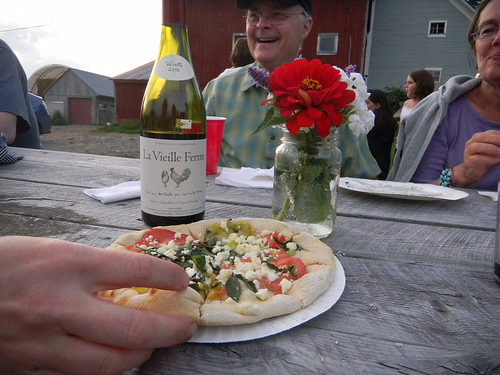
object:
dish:
[175, 251, 346, 345]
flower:
[246, 66, 272, 93]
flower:
[344, 63, 360, 78]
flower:
[334, 66, 376, 136]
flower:
[296, 53, 304, 61]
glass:
[202, 115, 226, 178]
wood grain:
[399, 231, 489, 263]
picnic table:
[0, 137, 496, 374]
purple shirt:
[415, 102, 496, 186]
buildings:
[133, 0, 500, 150]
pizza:
[66, 217, 337, 327]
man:
[195, 0, 385, 173]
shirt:
[184, 59, 379, 188]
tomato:
[288, 258, 305, 277]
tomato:
[265, 280, 283, 294]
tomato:
[266, 233, 284, 248]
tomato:
[135, 228, 200, 245]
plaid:
[230, 101, 240, 116]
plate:
[337, 176, 469, 204]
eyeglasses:
[242, 12, 307, 26]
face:
[243, 3, 300, 63]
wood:
[2, 144, 499, 371]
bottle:
[136, 0, 210, 230]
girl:
[394, 69, 449, 164]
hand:
[0, 234, 197, 373]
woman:
[392, 13, 498, 183]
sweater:
[393, 74, 470, 165]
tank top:
[399, 104, 414, 119]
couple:
[197, 2, 500, 177]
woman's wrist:
[433, 163, 469, 187]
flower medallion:
[438, 169, 453, 186]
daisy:
[257, 50, 359, 138]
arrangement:
[250, 58, 383, 145]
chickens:
[168, 167, 191, 188]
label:
[139, 135, 207, 216]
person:
[391, 65, 430, 168]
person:
[190, 3, 383, 178]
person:
[390, 5, 499, 190]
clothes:
[192, 65, 390, 185]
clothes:
[386, 74, 500, 185]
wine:
[134, 66, 200, 222]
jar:
[264, 121, 344, 242]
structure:
[22, 59, 140, 126]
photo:
[0, 3, 500, 375]